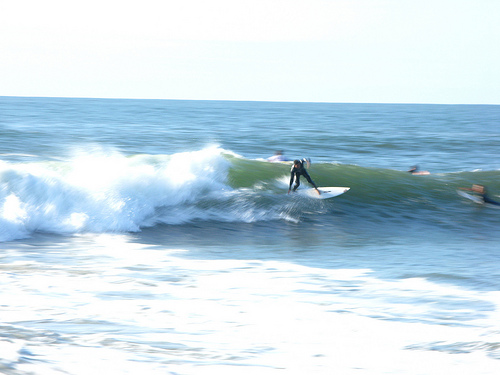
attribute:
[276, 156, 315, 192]
surfer — standing, here, bending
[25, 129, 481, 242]
wave — foamy, here, cresint, misty, breaking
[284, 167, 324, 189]
wetsuit — worn, black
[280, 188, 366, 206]
surfboard — white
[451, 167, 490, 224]
surfer — here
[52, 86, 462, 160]
ocean — calm, blue, here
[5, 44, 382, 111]
day — sunny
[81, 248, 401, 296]
water — here, calm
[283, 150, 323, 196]
person — paddling, surfing, leaning